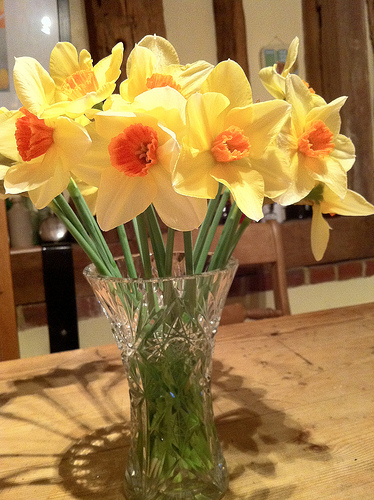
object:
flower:
[84, 65, 211, 230]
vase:
[78, 255, 240, 500]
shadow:
[0, 332, 329, 499]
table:
[0, 301, 374, 500]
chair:
[178, 217, 297, 328]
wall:
[160, 0, 216, 69]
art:
[249, 34, 308, 99]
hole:
[270, 328, 281, 338]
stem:
[181, 227, 197, 317]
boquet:
[13, 39, 356, 264]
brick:
[225, 242, 371, 303]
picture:
[260, 42, 287, 76]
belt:
[40, 240, 81, 356]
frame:
[254, 42, 312, 65]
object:
[160, 229, 313, 328]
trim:
[267, 251, 370, 303]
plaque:
[260, 44, 294, 73]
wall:
[243, 0, 306, 92]